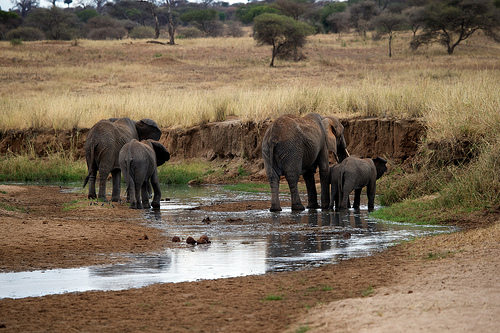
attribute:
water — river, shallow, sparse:
[1, 187, 476, 303]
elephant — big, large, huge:
[262, 113, 350, 213]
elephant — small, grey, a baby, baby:
[329, 155, 390, 212]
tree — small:
[248, 8, 312, 69]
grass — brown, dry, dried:
[5, 32, 499, 130]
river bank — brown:
[2, 200, 496, 332]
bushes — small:
[13, 6, 492, 35]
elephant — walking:
[116, 136, 167, 206]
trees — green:
[89, 2, 363, 28]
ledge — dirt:
[17, 122, 419, 164]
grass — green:
[1, 160, 211, 184]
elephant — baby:
[328, 151, 389, 206]